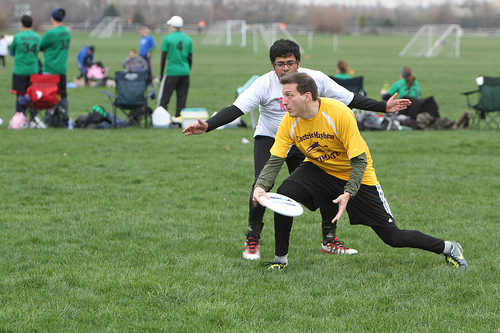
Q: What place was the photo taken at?
A: It was taken at the field.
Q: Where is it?
A: This is at the field.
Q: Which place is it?
A: It is a field.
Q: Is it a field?
A: Yes, it is a field.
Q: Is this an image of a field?
A: Yes, it is showing a field.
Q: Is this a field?
A: Yes, it is a field.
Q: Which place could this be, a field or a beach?
A: It is a field.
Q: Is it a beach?
A: No, it is a field.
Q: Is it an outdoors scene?
A: Yes, it is outdoors.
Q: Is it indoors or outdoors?
A: It is outdoors.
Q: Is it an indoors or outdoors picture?
A: It is outdoors.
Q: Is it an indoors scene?
A: No, it is outdoors.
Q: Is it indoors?
A: No, it is outdoors.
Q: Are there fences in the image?
A: No, there are no fences.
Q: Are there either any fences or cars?
A: No, there are no fences or cars.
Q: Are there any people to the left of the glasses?
A: Yes, there are people to the left of the glasses.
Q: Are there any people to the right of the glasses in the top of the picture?
A: No, the people are to the left of the glasses.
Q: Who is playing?
A: The people are playing.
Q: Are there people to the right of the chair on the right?
A: No, the people are to the left of the chair.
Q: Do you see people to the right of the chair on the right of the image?
A: No, the people are to the left of the chair.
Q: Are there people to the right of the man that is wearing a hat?
A: Yes, there are people to the right of the man.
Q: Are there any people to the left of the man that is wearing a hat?
A: No, the people are to the right of the man.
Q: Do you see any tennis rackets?
A: No, there are no tennis rackets.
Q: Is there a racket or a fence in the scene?
A: No, there are no rackets or fences.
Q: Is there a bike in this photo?
A: No, there are no bikes.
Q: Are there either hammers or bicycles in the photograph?
A: No, there are no bicycles or hammers.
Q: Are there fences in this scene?
A: No, there are no fences.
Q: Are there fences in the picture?
A: No, there are no fences.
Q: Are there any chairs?
A: Yes, there is a chair.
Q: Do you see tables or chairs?
A: Yes, there is a chair.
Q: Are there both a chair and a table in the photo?
A: No, there is a chair but no tables.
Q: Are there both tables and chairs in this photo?
A: No, there is a chair but no tables.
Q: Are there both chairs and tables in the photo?
A: No, there is a chair but no tables.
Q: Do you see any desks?
A: No, there are no desks.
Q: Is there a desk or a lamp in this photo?
A: No, there are no desks or lamps.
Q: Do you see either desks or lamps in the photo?
A: No, there are no desks or lamps.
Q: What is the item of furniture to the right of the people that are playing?
A: The piece of furniture is a chair.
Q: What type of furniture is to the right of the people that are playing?
A: The piece of furniture is a chair.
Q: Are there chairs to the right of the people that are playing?
A: Yes, there is a chair to the right of the people.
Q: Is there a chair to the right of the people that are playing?
A: Yes, there is a chair to the right of the people.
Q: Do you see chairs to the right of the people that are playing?
A: Yes, there is a chair to the right of the people.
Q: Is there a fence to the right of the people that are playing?
A: No, there is a chair to the right of the people.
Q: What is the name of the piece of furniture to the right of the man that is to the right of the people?
A: The piece of furniture is a chair.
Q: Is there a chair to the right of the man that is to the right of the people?
A: Yes, there is a chair to the right of the man.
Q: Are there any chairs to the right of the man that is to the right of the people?
A: Yes, there is a chair to the right of the man.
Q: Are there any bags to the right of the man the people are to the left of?
A: No, there is a chair to the right of the man.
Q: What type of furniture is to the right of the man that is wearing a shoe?
A: The piece of furniture is a chair.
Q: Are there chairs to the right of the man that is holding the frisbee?
A: Yes, there is a chair to the right of the man.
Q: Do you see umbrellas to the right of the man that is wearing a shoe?
A: No, there is a chair to the right of the man.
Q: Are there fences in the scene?
A: No, there are no fences.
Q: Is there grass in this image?
A: Yes, there is grass.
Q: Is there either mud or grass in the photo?
A: Yes, there is grass.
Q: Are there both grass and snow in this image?
A: No, there is grass but no snow.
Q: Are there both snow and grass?
A: No, there is grass but no snow.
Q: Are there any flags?
A: No, there are no flags.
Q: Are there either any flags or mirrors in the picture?
A: No, there are no flags or mirrors.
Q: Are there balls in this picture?
A: No, there are no balls.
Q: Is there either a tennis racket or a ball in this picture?
A: No, there are no balls or rackets.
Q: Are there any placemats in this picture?
A: No, there are no placemats.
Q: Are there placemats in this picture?
A: No, there are no placemats.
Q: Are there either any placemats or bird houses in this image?
A: No, there are no placemats or bird houses.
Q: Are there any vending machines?
A: No, there are no vending machines.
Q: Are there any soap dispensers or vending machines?
A: No, there are no vending machines or soap dispensers.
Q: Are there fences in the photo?
A: No, there are no fences.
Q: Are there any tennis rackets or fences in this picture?
A: No, there are no fences or tennis rackets.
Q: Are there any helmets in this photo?
A: No, there are no helmets.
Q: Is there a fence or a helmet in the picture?
A: No, there are no helmets or fences.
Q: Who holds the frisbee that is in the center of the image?
A: The man holds the frisbee.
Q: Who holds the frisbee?
A: The man holds the frisbee.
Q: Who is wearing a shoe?
A: The man is wearing a shoe.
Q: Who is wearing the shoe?
A: The man is wearing a shoe.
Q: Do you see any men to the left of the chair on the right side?
A: Yes, there is a man to the left of the chair.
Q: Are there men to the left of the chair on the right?
A: Yes, there is a man to the left of the chair.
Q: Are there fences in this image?
A: No, there are no fences.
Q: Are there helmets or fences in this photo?
A: No, there are no fences or helmets.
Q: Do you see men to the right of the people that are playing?
A: No, the man is to the left of the people.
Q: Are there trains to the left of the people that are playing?
A: No, there is a man to the left of the people.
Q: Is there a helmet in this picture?
A: No, there are no helmets.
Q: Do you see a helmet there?
A: No, there are no helmets.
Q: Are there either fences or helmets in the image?
A: No, there are no helmets or fences.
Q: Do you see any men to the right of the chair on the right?
A: No, the man is to the left of the chair.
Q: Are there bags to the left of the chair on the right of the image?
A: No, there is a man to the left of the chair.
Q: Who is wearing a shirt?
A: The man is wearing a shirt.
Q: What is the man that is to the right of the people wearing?
A: The man is wearing a shirt.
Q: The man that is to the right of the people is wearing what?
A: The man is wearing a shirt.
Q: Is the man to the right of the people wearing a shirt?
A: Yes, the man is wearing a shirt.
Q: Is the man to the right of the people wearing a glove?
A: No, the man is wearing a shirt.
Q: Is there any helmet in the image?
A: No, there are no helmets.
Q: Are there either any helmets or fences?
A: No, there are no helmets or fences.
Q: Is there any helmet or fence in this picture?
A: No, there are no helmets or fences.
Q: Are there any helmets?
A: No, there are no helmets.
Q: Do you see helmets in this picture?
A: No, there are no helmets.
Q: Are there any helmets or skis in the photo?
A: No, there are no helmets or skis.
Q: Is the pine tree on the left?
A: Yes, the pine tree is on the left of the image.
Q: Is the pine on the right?
A: No, the pine is on the left of the image.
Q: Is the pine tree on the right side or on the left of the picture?
A: The pine tree is on the left of the image.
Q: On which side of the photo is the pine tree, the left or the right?
A: The pine tree is on the left of the image.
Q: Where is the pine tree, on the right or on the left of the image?
A: The pine tree is on the left of the image.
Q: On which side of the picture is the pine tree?
A: The pine tree is on the left of the image.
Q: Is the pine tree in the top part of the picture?
A: Yes, the pine tree is in the top of the image.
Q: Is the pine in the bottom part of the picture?
A: No, the pine is in the top of the image.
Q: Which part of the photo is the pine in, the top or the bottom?
A: The pine is in the top of the image.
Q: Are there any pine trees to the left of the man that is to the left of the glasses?
A: Yes, there is a pine tree to the left of the man.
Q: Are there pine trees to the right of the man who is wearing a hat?
A: No, the pine tree is to the left of the man.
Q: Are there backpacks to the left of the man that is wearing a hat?
A: No, there is a pine tree to the left of the man.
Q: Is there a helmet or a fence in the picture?
A: No, there are no helmets or fences.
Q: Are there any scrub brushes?
A: No, there are no scrub brushes.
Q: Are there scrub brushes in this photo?
A: No, there are no scrub brushes.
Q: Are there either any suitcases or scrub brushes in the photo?
A: No, there are no scrub brushes or suitcases.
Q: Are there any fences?
A: No, there are no fences.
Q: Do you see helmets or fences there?
A: No, there are no fences or helmets.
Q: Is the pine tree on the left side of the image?
A: Yes, the pine tree is on the left of the image.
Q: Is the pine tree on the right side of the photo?
A: No, the pine tree is on the left of the image.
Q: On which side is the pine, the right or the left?
A: The pine is on the left of the image.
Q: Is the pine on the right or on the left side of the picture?
A: The pine is on the left of the image.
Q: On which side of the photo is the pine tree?
A: The pine tree is on the left of the image.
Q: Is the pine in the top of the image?
A: Yes, the pine is in the top of the image.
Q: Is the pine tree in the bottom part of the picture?
A: No, the pine tree is in the top of the image.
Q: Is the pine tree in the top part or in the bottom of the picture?
A: The pine tree is in the top of the image.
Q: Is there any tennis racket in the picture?
A: No, there are no rackets.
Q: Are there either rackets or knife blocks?
A: No, there are no rackets or knife blocks.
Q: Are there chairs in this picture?
A: Yes, there is a chair.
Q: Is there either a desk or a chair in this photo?
A: Yes, there is a chair.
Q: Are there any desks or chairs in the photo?
A: Yes, there is a chair.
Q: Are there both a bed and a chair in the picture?
A: No, there is a chair but no beds.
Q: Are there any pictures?
A: No, there are no pictures.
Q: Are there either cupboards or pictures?
A: No, there are no pictures or cupboards.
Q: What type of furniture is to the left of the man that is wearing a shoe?
A: The piece of furniture is a chair.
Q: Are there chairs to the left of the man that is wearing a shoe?
A: Yes, there is a chair to the left of the man.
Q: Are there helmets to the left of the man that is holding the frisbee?
A: No, there is a chair to the left of the man.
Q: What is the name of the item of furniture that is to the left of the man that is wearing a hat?
A: The piece of furniture is a chair.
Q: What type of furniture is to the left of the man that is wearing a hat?
A: The piece of furniture is a chair.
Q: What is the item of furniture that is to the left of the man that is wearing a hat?
A: The piece of furniture is a chair.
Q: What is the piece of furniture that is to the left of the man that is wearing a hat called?
A: The piece of furniture is a chair.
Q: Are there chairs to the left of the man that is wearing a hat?
A: Yes, there is a chair to the left of the man.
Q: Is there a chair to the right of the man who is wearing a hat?
A: No, the chair is to the left of the man.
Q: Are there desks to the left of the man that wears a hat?
A: No, there is a chair to the left of the man.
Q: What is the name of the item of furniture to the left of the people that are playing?
A: The piece of furniture is a chair.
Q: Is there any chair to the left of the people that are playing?
A: Yes, there is a chair to the left of the people.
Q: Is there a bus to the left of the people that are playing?
A: No, there is a chair to the left of the people.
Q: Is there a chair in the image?
A: Yes, there is a chair.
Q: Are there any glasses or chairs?
A: Yes, there is a chair.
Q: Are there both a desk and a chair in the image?
A: No, there is a chair but no desks.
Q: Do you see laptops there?
A: No, there are no laptops.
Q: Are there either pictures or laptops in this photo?
A: No, there are no laptops or pictures.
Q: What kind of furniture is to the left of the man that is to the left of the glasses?
A: The piece of furniture is a chair.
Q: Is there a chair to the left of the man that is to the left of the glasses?
A: Yes, there is a chair to the left of the man.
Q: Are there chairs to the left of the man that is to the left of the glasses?
A: Yes, there is a chair to the left of the man.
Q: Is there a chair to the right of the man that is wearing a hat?
A: No, the chair is to the left of the man.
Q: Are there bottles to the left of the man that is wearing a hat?
A: No, there is a chair to the left of the man.